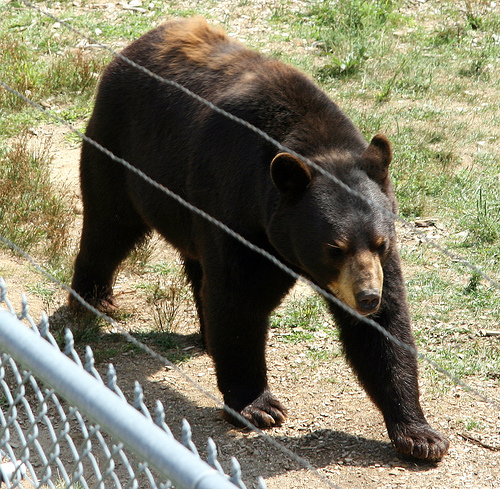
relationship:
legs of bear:
[204, 279, 442, 459] [82, 33, 452, 434]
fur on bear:
[159, 12, 215, 63] [32, 20, 447, 467]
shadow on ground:
[0, 306, 312, 481] [10, 7, 498, 483]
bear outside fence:
[32, 20, 447, 467] [7, 9, 381, 485]